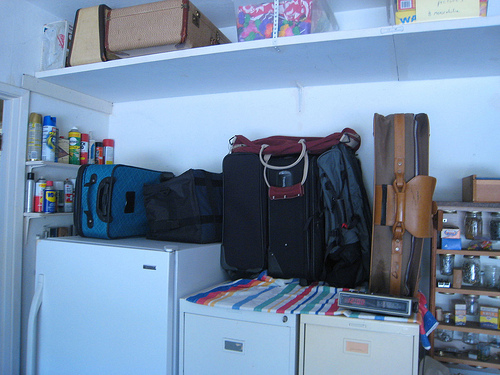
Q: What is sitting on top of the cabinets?
A: Luggage.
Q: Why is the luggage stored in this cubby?
A: To save space.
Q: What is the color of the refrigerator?
A: White.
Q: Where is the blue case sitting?
A: On the fridge.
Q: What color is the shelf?
A: White.